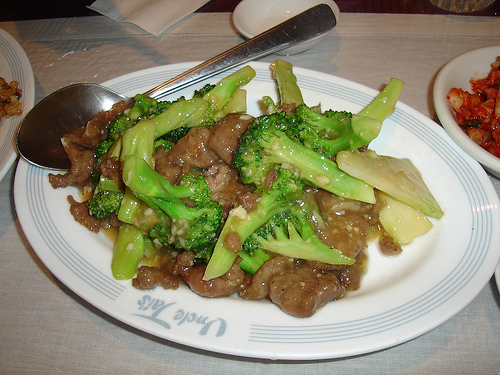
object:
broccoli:
[107, 93, 217, 139]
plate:
[10, 59, 496, 362]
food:
[46, 59, 444, 319]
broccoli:
[244, 209, 356, 266]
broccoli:
[201, 168, 304, 281]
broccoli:
[285, 102, 383, 159]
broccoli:
[122, 155, 224, 253]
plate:
[431, 45, 499, 177]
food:
[446, 56, 500, 159]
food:
[0, 76, 23, 122]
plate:
[0, 28, 36, 183]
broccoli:
[231, 110, 376, 205]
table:
[337, 24, 433, 77]